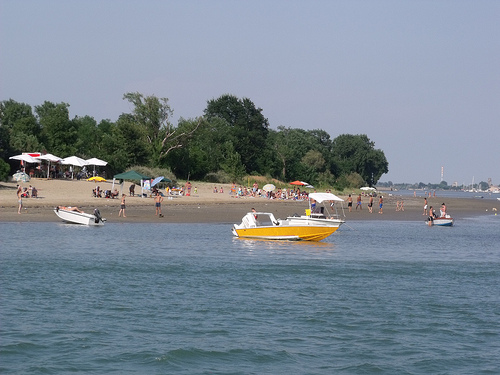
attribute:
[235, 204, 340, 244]
motor boat — yellow, white, distant, in water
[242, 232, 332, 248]
hull — yellow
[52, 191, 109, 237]
white boat — blue, on beach, on shore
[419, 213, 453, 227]
motor boat — white, red white, blue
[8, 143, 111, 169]
umbrellas — rowed, white, clustered, on beach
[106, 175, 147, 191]
canopy — green, 4 posted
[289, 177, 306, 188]
umbrella — orange, white, yellow, red, on beach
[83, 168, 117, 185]
umbrella — yellow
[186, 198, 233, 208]
sand — wet, tan, brown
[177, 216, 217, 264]
water — blue, calm, green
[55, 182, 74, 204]
sand — dry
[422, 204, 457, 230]
boat — red, white, small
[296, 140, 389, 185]
trees — green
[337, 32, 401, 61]
sky — blue, clear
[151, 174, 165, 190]
umbrella — green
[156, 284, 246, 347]
waves — in water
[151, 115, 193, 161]
tree — bare